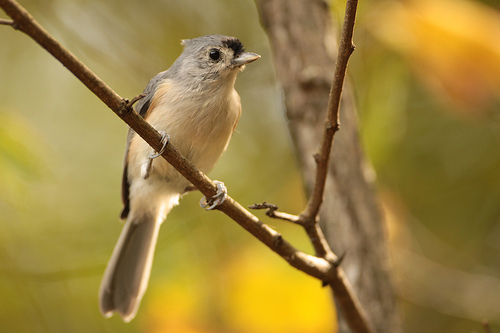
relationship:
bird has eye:
[91, 31, 267, 326] [211, 46, 227, 66]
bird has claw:
[91, 31, 267, 326] [199, 174, 232, 214]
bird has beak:
[91, 31, 267, 326] [230, 51, 264, 67]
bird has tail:
[91, 31, 267, 326] [97, 207, 173, 322]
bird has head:
[91, 31, 267, 326] [174, 28, 268, 90]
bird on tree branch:
[91, 31, 267, 326] [0, 0, 371, 332]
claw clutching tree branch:
[199, 174, 232, 214] [0, 0, 371, 332]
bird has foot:
[91, 31, 267, 326] [148, 126, 171, 161]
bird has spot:
[91, 31, 267, 326] [230, 33, 247, 55]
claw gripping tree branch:
[199, 174, 232, 214] [0, 0, 371, 332]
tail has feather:
[97, 207, 173, 322] [121, 223, 158, 318]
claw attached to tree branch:
[199, 174, 232, 214] [0, 0, 371, 332]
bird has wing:
[91, 31, 267, 326] [116, 76, 176, 219]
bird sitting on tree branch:
[91, 31, 267, 326] [0, 0, 371, 332]